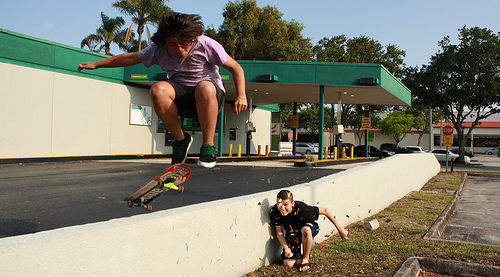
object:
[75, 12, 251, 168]
boy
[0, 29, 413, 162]
building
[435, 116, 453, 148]
sign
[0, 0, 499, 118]
sky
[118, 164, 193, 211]
skateboard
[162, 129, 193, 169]
feet